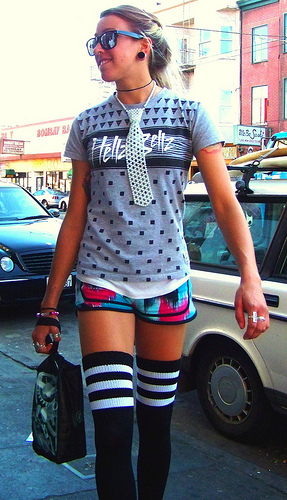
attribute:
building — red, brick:
[241, 0, 286, 146]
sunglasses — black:
[88, 32, 147, 56]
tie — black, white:
[114, 81, 156, 208]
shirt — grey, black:
[64, 89, 224, 284]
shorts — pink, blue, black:
[75, 278, 199, 325]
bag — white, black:
[31, 314, 86, 463]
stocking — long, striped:
[83, 351, 138, 499]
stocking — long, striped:
[136, 355, 184, 498]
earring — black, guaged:
[135, 52, 147, 60]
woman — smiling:
[31, 4, 273, 496]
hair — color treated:
[99, 5, 181, 90]